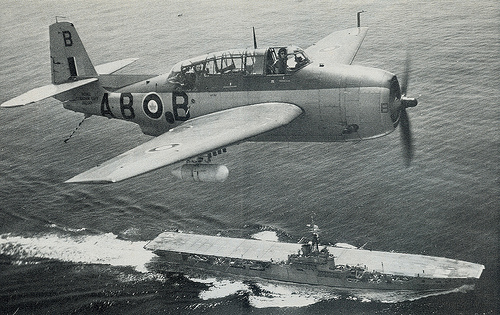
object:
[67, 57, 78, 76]
stripe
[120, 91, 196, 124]
bob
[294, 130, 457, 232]
ground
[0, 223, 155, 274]
wave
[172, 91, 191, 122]
letter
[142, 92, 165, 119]
letter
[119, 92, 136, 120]
letter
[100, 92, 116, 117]
letter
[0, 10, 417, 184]
aircraft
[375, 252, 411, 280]
ground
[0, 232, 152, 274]
wake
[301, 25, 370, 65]
wing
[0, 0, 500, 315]
water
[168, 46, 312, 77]
cockpit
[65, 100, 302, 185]
wing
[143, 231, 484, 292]
aircraft carrier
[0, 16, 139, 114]
tailfin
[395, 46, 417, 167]
propeller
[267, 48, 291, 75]
pilot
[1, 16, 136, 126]
tail